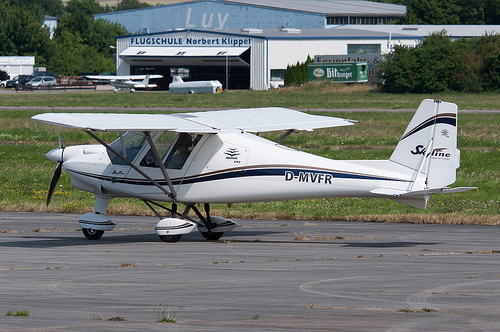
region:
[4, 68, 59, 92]
two parked cars parked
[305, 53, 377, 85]
green box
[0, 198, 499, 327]
grass sticking out of the pavement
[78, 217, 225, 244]
wheels of the airplane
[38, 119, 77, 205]
airplane propellers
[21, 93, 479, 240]
a small airplane on the runway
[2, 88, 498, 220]
patch of grass by the airport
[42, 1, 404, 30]
top of a large blue building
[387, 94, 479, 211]
tail of an airplane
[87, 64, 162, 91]
a plane outside of the airport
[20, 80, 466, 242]
a white plane on a landing strip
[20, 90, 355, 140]
wings of plane are rectangular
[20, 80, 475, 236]
a white small aircraft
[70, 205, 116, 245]
front wheel of aircraft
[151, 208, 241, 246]
back wheels of aircraft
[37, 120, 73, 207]
propeller in front of plane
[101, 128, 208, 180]
cockpit of aircraft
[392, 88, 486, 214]
fins on tail of aircraft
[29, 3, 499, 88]
buildings on side of landing strip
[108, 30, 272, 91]
front building has a wide door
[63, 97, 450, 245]
the plane is white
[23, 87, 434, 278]
the plane is on runway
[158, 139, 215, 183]
the guy is on the cockpit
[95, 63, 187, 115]
plane is in the background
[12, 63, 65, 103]
the cars are parked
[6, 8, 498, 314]
the scene is in an airpot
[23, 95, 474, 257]
the plane has thre wheels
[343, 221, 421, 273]
shadow is on the ground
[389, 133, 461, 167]
the mdel is skyline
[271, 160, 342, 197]
d-mvfrr is written on the plane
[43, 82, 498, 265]
The plane is on the runway.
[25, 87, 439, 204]
The plane is white.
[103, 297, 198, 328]
Grass on the pavement.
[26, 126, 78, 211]
The propeller in the front.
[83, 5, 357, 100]
A building on the other side of runway.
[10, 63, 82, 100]
Cars parked by the building.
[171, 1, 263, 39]
The building has the word "LUV" on it.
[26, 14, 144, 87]
Trees next to the building.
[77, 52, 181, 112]
A plane in front of the building.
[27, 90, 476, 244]
white airplane with black trim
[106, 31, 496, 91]
white airplane hanger with open doors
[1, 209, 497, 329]
airplane wheels on concrete runway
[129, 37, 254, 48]
german words on airplane hanger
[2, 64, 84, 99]
vehicles parked next to hanger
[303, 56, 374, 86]
green trailer with lettering next to hanger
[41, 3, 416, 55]
larger light blue building behind hanger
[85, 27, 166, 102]
airplane in front of hanger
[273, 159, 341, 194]
airplane identification on side of plane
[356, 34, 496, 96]
group of green bushes